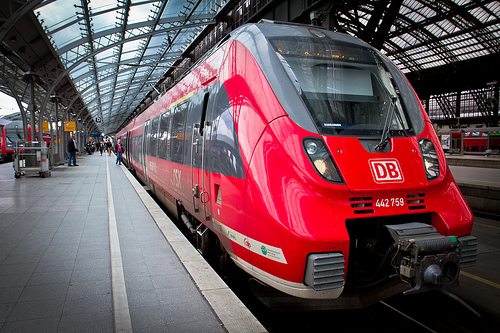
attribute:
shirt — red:
[114, 143, 133, 154]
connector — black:
[391, 246, 457, 301]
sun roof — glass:
[19, 6, 492, 148]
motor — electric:
[381, 220, 463, 297]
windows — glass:
[33, 2, 228, 134]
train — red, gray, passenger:
[123, 30, 465, 299]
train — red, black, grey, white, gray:
[102, 12, 485, 326]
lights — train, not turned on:
[298, 127, 448, 188]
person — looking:
[61, 132, 81, 168]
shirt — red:
[116, 140, 122, 151]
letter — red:
[374, 162, 388, 178]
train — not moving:
[79, 28, 490, 310]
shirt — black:
[67, 138, 75, 148]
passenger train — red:
[145, 41, 475, 313]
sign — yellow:
[62, 119, 76, 132]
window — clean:
[260, 33, 430, 146]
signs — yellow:
[28, 103, 96, 145]